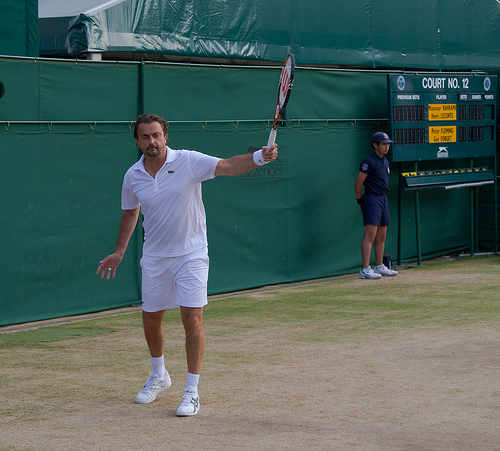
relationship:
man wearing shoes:
[92, 114, 277, 417] [135, 370, 200, 415]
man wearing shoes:
[354, 132, 400, 278] [357, 261, 396, 280]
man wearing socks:
[92, 114, 277, 417] [150, 352, 200, 385]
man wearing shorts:
[92, 114, 277, 417] [139, 254, 211, 313]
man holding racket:
[92, 114, 277, 417] [266, 53, 294, 149]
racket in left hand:
[266, 53, 294, 149] [263, 144, 278, 163]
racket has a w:
[266, 53, 294, 149] [280, 71, 291, 93]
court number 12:
[1, 1, 496, 450] [460, 78, 469, 89]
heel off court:
[155, 372, 174, 391] [1, 1, 496, 450]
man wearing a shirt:
[92, 114, 277, 417] [120, 150, 221, 260]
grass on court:
[0, 240, 499, 451] [1, 1, 496, 450]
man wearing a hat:
[354, 132, 400, 278] [370, 131, 392, 145]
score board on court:
[385, 70, 497, 264] [1, 1, 496, 450]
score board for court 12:
[385, 70, 497, 264] [460, 78, 469, 89]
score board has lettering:
[385, 70, 497, 264] [397, 74, 493, 101]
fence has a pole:
[3, 53, 496, 328] [135, 61, 146, 295]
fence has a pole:
[3, 53, 496, 328] [383, 73, 391, 133]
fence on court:
[3, 53, 496, 328] [1, 1, 496, 450]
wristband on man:
[251, 148, 269, 165] [92, 114, 277, 417]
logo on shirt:
[166, 167, 172, 173] [120, 150, 221, 260]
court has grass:
[1, 1, 496, 450] [0, 240, 499, 451]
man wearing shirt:
[92, 114, 277, 417] [120, 150, 221, 260]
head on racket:
[275, 52, 294, 113] [266, 53, 294, 149]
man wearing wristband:
[92, 114, 277, 417] [251, 148, 269, 165]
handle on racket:
[265, 119, 279, 145] [266, 53, 294, 149]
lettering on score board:
[397, 74, 493, 101] [385, 70, 497, 264]